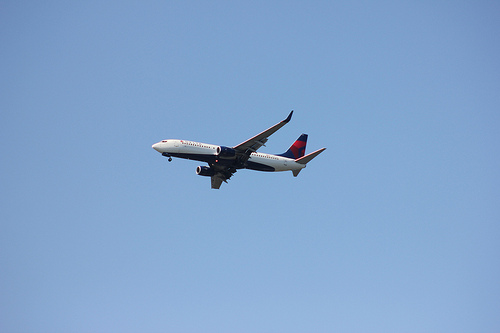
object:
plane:
[148, 109, 328, 191]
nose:
[139, 137, 167, 157]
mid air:
[74, 61, 391, 261]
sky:
[5, 2, 498, 98]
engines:
[191, 143, 241, 182]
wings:
[193, 106, 297, 193]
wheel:
[166, 153, 175, 166]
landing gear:
[164, 150, 179, 165]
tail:
[285, 131, 312, 158]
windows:
[270, 156, 274, 159]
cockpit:
[147, 134, 177, 156]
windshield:
[159, 138, 170, 145]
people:
[200, 141, 213, 149]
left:
[4, 1, 32, 329]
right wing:
[231, 107, 297, 152]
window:
[156, 137, 169, 146]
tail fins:
[297, 144, 334, 168]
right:
[465, 4, 498, 332]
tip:
[278, 104, 298, 130]